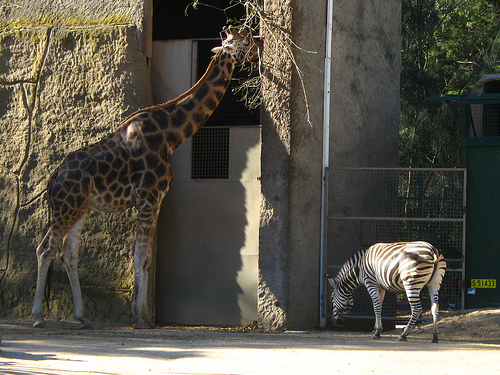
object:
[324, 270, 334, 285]
left ear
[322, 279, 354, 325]
head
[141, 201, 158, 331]
legs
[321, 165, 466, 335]
fence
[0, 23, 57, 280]
crack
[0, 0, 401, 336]
building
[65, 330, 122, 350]
shadow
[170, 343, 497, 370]
ground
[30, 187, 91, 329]
giraffe`s legs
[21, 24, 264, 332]
giraffe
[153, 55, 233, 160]
neck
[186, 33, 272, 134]
opening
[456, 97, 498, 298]
partition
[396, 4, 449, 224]
tree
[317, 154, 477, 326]
chain link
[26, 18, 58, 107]
wall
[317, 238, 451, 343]
zebra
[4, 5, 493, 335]
enclosure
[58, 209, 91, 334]
legs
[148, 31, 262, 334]
door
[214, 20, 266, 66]
head